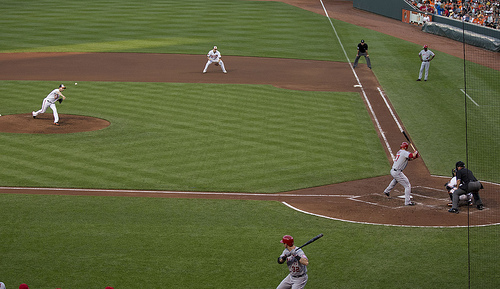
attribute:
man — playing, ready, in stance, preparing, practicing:
[203, 46, 228, 75]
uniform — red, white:
[384, 151, 414, 199]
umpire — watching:
[453, 160, 485, 216]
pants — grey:
[451, 182, 483, 206]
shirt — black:
[456, 168, 479, 184]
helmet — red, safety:
[399, 142, 409, 149]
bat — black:
[403, 129, 420, 153]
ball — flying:
[72, 82, 79, 86]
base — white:
[351, 82, 365, 90]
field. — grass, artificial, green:
[3, 3, 499, 288]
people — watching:
[477, 6, 488, 19]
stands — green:
[351, 1, 499, 52]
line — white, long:
[320, 11, 420, 202]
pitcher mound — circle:
[3, 110, 108, 136]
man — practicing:
[278, 234, 314, 285]